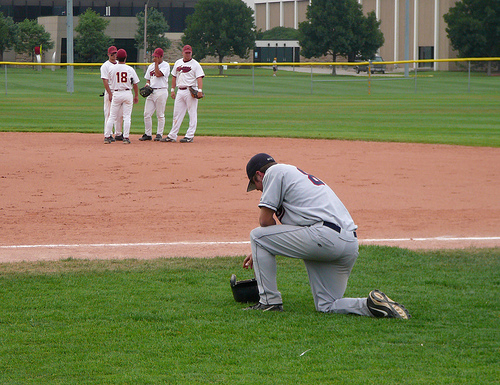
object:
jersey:
[170, 58, 203, 89]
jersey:
[143, 62, 173, 88]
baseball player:
[241, 150, 411, 323]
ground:
[0, 63, 500, 383]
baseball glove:
[229, 275, 263, 305]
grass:
[0, 61, 500, 383]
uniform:
[252, 159, 357, 228]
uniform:
[109, 62, 141, 93]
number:
[116, 70, 130, 83]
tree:
[296, 0, 386, 78]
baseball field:
[4, 59, 499, 378]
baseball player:
[100, 44, 124, 136]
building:
[256, 0, 490, 73]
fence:
[0, 59, 500, 94]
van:
[351, 52, 385, 75]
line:
[0, 236, 500, 249]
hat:
[238, 152, 278, 192]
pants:
[250, 220, 377, 318]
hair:
[254, 161, 278, 175]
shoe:
[365, 289, 411, 320]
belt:
[322, 218, 358, 239]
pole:
[66, 0, 76, 91]